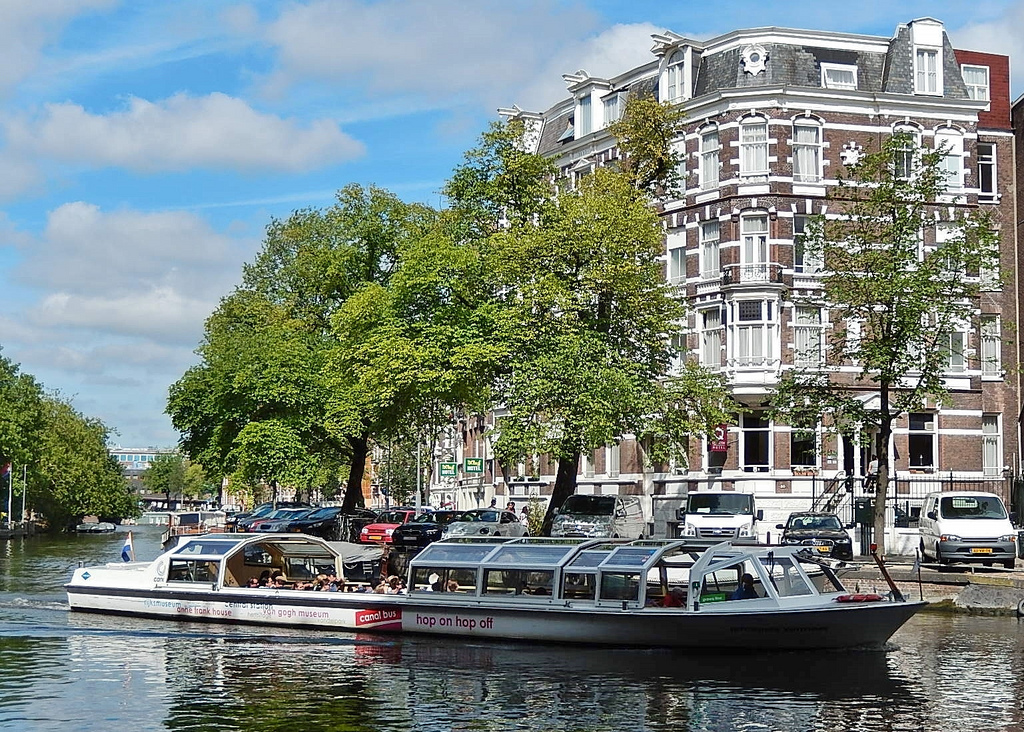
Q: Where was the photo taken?
A: In a metro area by the lakeside.